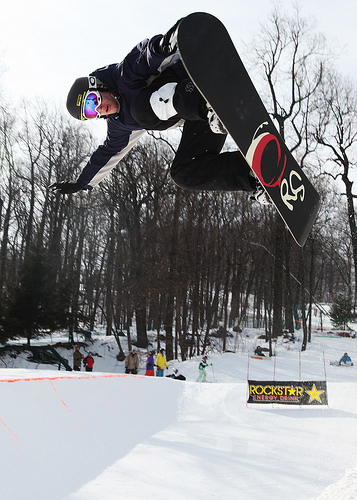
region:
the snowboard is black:
[150, 5, 355, 244]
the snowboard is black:
[171, 2, 325, 258]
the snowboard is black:
[169, 27, 353, 270]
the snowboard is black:
[168, 15, 337, 308]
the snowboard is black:
[178, 26, 333, 285]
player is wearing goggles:
[39, 60, 130, 142]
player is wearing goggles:
[58, 74, 133, 139]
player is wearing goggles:
[59, 70, 141, 141]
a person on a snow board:
[42, 7, 328, 245]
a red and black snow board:
[166, 6, 328, 251]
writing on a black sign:
[243, 377, 331, 403]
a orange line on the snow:
[14, 368, 170, 395]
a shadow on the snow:
[145, 423, 324, 489]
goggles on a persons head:
[80, 77, 96, 120]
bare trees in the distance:
[81, 209, 255, 338]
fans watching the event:
[73, 346, 214, 371]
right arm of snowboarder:
[54, 130, 134, 205]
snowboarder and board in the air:
[45, 11, 328, 251]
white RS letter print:
[276, 169, 313, 212]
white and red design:
[234, 120, 293, 188]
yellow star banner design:
[304, 384, 326, 403]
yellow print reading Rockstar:
[248, 383, 306, 396]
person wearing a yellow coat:
[154, 346, 170, 375]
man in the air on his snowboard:
[49, 10, 333, 248]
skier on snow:
[194, 354, 218, 383]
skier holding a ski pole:
[194, 354, 218, 384]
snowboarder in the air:
[64, 17, 326, 253]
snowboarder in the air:
[80, 10, 328, 269]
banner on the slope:
[233, 377, 335, 412]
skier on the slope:
[194, 354, 217, 384]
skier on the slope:
[153, 345, 175, 381]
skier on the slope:
[125, 346, 146, 378]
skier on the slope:
[86, 350, 96, 374]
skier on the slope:
[324, 348, 350, 372]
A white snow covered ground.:
[0, 328, 355, 497]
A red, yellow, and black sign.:
[244, 380, 330, 409]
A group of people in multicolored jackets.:
[70, 344, 215, 385]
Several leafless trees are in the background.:
[0, 103, 355, 358]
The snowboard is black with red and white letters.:
[175, 6, 335, 251]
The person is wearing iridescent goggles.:
[84, 75, 100, 121]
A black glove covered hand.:
[49, 179, 88, 196]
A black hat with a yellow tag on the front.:
[63, 75, 87, 122]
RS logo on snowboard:
[274, 164, 309, 221]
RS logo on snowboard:
[271, 163, 310, 216]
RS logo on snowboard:
[273, 165, 316, 220]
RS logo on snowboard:
[265, 166, 316, 221]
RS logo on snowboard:
[270, 161, 321, 221]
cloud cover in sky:
[0, 1, 355, 188]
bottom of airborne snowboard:
[176, 12, 320, 246]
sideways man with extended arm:
[51, 17, 270, 202]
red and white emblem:
[242, 121, 305, 209]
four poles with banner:
[245, 350, 328, 404]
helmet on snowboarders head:
[66, 75, 120, 120]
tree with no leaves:
[308, 67, 354, 278]